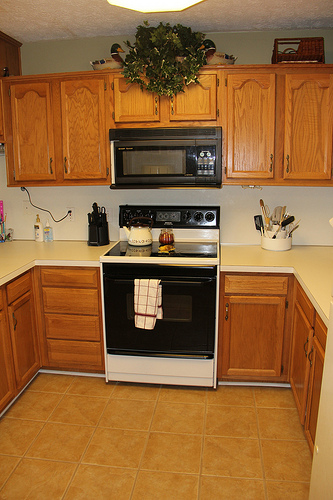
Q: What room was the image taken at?
A: It was taken at the kitchen.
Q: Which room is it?
A: It is a kitchen.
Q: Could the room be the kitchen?
A: Yes, it is the kitchen.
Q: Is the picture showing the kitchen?
A: Yes, it is showing the kitchen.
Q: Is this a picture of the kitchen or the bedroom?
A: It is showing the kitchen.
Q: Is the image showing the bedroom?
A: No, the picture is showing the kitchen.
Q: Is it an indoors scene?
A: Yes, it is indoors.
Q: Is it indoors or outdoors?
A: It is indoors.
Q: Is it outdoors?
A: No, it is indoors.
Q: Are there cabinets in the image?
A: Yes, there is a cabinet.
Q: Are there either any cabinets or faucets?
A: Yes, there is a cabinet.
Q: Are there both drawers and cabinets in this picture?
A: Yes, there are both a cabinet and drawers.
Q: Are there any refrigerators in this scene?
A: No, there are no refrigerators.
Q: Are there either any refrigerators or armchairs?
A: No, there are no refrigerators or armchairs.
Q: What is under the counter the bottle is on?
A: The cabinet is under the counter.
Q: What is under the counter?
A: The cabinet is under the counter.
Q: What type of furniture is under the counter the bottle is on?
A: The piece of furniture is a cabinet.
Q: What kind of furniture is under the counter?
A: The piece of furniture is a cabinet.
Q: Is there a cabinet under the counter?
A: Yes, there is a cabinet under the counter.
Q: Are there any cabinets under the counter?
A: Yes, there is a cabinet under the counter.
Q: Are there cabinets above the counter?
A: No, the cabinet is under the counter.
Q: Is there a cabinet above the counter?
A: No, the cabinet is under the counter.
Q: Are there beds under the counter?
A: No, there is a cabinet under the counter.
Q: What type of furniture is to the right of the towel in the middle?
A: The piece of furniture is a cabinet.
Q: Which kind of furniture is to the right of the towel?
A: The piece of furniture is a cabinet.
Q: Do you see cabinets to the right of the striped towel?
A: Yes, there is a cabinet to the right of the towel.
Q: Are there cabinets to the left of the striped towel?
A: No, the cabinet is to the right of the towel.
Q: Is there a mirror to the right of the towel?
A: No, there is a cabinet to the right of the towel.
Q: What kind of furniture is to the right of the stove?
A: The piece of furniture is a cabinet.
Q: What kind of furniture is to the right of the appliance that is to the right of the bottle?
A: The piece of furniture is a cabinet.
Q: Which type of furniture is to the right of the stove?
A: The piece of furniture is a cabinet.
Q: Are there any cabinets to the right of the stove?
A: Yes, there is a cabinet to the right of the stove.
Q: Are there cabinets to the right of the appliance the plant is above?
A: Yes, there is a cabinet to the right of the stove.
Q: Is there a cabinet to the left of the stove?
A: No, the cabinet is to the right of the stove.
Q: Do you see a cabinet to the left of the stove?
A: No, the cabinet is to the right of the stove.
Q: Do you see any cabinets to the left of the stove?
A: No, the cabinet is to the right of the stove.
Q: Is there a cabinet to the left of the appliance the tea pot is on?
A: No, the cabinet is to the right of the stove.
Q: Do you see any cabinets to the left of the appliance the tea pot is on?
A: No, the cabinet is to the right of the stove.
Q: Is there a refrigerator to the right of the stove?
A: No, there is a cabinet to the right of the stove.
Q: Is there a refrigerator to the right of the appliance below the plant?
A: No, there is a cabinet to the right of the stove.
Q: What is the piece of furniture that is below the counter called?
A: The piece of furniture is a cabinet.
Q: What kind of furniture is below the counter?
A: The piece of furniture is a cabinet.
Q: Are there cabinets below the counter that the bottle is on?
A: Yes, there is a cabinet below the counter.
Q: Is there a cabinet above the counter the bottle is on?
A: No, the cabinet is below the counter.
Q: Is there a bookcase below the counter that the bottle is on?
A: No, there is a cabinet below the counter.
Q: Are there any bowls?
A: No, there are no bowls.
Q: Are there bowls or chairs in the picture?
A: No, there are no bowls or chairs.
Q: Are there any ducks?
A: Yes, there is a duck.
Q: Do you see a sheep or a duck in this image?
A: Yes, there is a duck.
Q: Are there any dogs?
A: No, there are no dogs.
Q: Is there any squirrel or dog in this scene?
A: No, there are no dogs or squirrels.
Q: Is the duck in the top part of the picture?
A: Yes, the duck is in the top of the image.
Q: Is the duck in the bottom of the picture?
A: No, the duck is in the top of the image.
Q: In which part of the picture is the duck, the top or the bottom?
A: The duck is in the top of the image.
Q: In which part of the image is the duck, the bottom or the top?
A: The duck is in the top of the image.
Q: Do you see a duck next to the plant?
A: Yes, there is a duck next to the plant.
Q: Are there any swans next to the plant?
A: No, there is a duck next to the plant.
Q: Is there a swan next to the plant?
A: No, there is a duck next to the plant.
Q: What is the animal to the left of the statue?
A: The animal is a duck.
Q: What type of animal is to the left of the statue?
A: The animal is a duck.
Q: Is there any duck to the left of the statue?
A: Yes, there is a duck to the left of the statue.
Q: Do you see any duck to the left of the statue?
A: Yes, there is a duck to the left of the statue.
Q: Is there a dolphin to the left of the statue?
A: No, there is a duck to the left of the statue.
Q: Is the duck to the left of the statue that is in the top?
A: Yes, the duck is to the left of the statue.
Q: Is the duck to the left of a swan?
A: No, the duck is to the left of the statue.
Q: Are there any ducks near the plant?
A: Yes, there is a duck near the plant.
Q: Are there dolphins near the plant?
A: No, there is a duck near the plant.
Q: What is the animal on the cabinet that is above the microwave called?
A: The animal is a duck.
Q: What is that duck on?
A: The duck is on the cabinet.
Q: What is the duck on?
A: The duck is on the cabinet.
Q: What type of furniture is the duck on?
A: The duck is on the cabinet.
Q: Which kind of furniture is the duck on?
A: The duck is on the cabinet.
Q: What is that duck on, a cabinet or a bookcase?
A: The duck is on a cabinet.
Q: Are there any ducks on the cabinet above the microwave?
A: Yes, there is a duck on the cabinet.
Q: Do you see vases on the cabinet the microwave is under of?
A: No, there is a duck on the cabinet.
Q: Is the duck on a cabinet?
A: Yes, the duck is on a cabinet.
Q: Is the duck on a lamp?
A: No, the duck is on a cabinet.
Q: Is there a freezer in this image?
A: No, there are no refrigerators.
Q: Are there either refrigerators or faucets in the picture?
A: No, there are no refrigerators or faucets.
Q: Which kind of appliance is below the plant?
A: The appliance is a stove.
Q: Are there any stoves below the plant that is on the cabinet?
A: Yes, there is a stove below the plant.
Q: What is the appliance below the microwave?
A: The appliance is a stove.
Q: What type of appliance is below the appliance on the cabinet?
A: The appliance is a stove.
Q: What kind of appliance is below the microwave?
A: The appliance is a stove.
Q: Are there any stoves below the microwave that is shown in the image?
A: Yes, there is a stove below the microwave.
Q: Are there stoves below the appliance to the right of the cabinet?
A: Yes, there is a stove below the microwave.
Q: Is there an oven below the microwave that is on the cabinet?
A: No, there is a stove below the microwave.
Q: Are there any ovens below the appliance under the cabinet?
A: No, there is a stove below the microwave.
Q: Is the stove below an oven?
A: No, the stove is below the microwave.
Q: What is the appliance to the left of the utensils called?
A: The appliance is a stove.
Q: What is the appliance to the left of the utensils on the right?
A: The appliance is a stove.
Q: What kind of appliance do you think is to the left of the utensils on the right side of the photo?
A: The appliance is a stove.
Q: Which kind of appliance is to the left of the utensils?
A: The appliance is a stove.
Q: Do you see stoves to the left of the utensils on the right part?
A: Yes, there is a stove to the left of the utensils.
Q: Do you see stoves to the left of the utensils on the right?
A: Yes, there is a stove to the left of the utensils.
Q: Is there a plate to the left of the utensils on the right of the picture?
A: No, there is a stove to the left of the utensils.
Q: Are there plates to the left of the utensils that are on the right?
A: No, there is a stove to the left of the utensils.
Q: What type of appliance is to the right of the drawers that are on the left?
A: The appliance is a stove.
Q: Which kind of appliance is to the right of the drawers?
A: The appliance is a stove.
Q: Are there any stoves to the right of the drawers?
A: Yes, there is a stove to the right of the drawers.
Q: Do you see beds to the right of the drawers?
A: No, there is a stove to the right of the drawers.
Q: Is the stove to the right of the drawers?
A: Yes, the stove is to the right of the drawers.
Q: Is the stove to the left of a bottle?
A: No, the stove is to the right of a bottle.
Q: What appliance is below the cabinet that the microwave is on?
A: The appliance is a stove.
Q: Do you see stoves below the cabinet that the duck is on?
A: Yes, there is a stove below the cabinet.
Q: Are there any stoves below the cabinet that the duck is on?
A: Yes, there is a stove below the cabinet.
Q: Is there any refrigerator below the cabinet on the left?
A: No, there is a stove below the cabinet.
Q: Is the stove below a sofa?
A: No, the stove is below a cabinet.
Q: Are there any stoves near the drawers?
A: Yes, there is a stove near the drawers.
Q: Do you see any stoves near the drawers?
A: Yes, there is a stove near the drawers.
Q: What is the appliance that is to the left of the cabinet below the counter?
A: The appliance is a stove.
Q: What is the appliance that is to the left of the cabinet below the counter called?
A: The appliance is a stove.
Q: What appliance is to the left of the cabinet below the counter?
A: The appliance is a stove.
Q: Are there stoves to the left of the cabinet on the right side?
A: Yes, there is a stove to the left of the cabinet.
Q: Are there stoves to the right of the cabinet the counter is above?
A: No, the stove is to the left of the cabinet.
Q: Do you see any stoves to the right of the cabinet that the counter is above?
A: No, the stove is to the left of the cabinet.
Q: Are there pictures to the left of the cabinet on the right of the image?
A: No, there is a stove to the left of the cabinet.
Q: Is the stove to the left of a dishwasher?
A: No, the stove is to the left of the cabinet.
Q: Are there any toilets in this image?
A: No, there are no toilets.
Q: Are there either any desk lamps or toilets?
A: No, there are no toilets or desk lamps.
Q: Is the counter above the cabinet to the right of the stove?
A: Yes, the counter is above the cabinet.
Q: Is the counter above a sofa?
A: No, the counter is above the cabinet.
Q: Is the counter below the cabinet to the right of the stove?
A: No, the counter is above the cabinet.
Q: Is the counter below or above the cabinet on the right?
A: The counter is above the cabinet.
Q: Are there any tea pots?
A: Yes, there is a tea pot.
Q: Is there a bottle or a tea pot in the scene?
A: Yes, there is a tea pot.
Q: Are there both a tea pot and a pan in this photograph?
A: No, there is a tea pot but no pans.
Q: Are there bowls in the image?
A: No, there are no bowls.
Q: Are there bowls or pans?
A: No, there are no bowls or pans.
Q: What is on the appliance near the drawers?
A: The tea pot is on the stove.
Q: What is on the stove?
A: The tea pot is on the stove.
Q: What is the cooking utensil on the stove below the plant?
A: The cooking utensil is a tea pot.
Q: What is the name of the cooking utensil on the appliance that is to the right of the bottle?
A: The cooking utensil is a tea pot.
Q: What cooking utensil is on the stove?
A: The cooking utensil is a tea pot.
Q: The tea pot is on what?
A: The tea pot is on the stove.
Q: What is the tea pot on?
A: The tea pot is on the stove.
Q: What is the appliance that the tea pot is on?
A: The appliance is a stove.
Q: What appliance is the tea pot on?
A: The tea pot is on the stove.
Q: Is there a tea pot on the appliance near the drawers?
A: Yes, there is a tea pot on the stove.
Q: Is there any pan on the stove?
A: No, there is a tea pot on the stove.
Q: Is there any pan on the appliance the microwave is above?
A: No, there is a tea pot on the stove.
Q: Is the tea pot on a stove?
A: Yes, the tea pot is on a stove.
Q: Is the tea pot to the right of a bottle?
A: Yes, the tea pot is to the right of a bottle.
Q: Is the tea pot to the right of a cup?
A: No, the tea pot is to the right of a bottle.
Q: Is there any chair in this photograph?
A: No, there are no chairs.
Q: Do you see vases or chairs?
A: No, there are no chairs or vases.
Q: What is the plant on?
A: The plant is on the cabinet.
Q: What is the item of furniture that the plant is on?
A: The piece of furniture is a cabinet.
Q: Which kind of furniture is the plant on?
A: The plant is on the cabinet.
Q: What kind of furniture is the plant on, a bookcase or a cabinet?
A: The plant is on a cabinet.